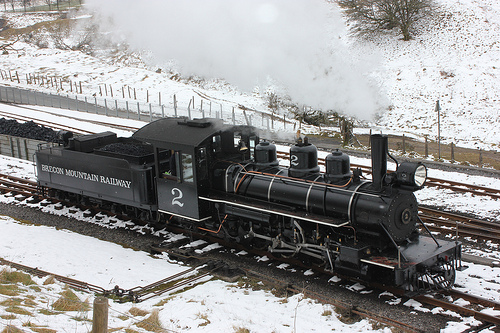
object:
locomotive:
[30, 116, 465, 293]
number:
[168, 186, 186, 211]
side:
[154, 180, 198, 219]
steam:
[69, 0, 393, 124]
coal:
[118, 143, 143, 155]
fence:
[1, 90, 219, 122]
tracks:
[427, 181, 500, 197]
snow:
[43, 240, 90, 271]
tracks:
[421, 222, 499, 239]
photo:
[0, 0, 500, 333]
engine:
[225, 133, 463, 292]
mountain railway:
[62, 168, 132, 189]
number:
[398, 171, 410, 185]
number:
[399, 208, 412, 226]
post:
[92, 296, 106, 333]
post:
[15, 70, 21, 86]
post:
[23, 0, 28, 18]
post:
[3, 0, 9, 13]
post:
[78, 81, 84, 96]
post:
[68, 79, 73, 97]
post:
[25, 72, 30, 87]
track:
[0, 176, 500, 333]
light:
[396, 162, 427, 190]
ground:
[0, 198, 383, 332]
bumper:
[406, 260, 457, 292]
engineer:
[160, 148, 192, 183]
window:
[176, 151, 194, 184]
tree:
[330, 0, 437, 41]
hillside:
[343, 0, 499, 130]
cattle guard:
[409, 258, 456, 292]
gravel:
[418, 311, 439, 325]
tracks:
[427, 294, 500, 326]